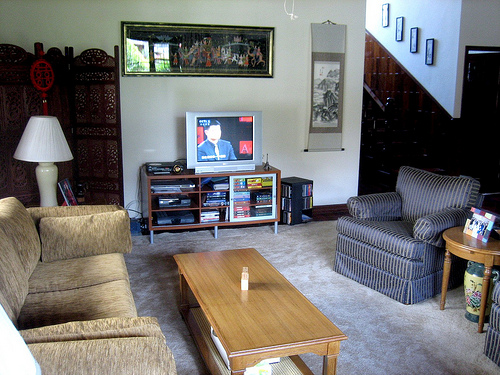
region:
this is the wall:
[138, 99, 159, 121]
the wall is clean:
[149, 99, 163, 126]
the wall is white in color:
[150, 121, 165, 136]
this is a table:
[176, 262, 311, 357]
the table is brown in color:
[235, 301, 275, 341]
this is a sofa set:
[27, 217, 137, 352]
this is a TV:
[186, 104, 263, 162]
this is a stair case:
[395, 57, 425, 108]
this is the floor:
[380, 316, 408, 345]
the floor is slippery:
[366, 332, 395, 358]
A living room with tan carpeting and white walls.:
[3, 1, 499, 374]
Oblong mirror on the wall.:
[116, 22, 274, 82]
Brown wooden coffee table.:
[173, 246, 345, 374]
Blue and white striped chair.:
[332, 161, 485, 303]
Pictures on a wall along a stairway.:
[380, 2, 440, 66]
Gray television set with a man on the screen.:
[184, 114, 266, 174]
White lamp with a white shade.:
[14, 116, 74, 206]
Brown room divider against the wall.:
[0, 38, 124, 215]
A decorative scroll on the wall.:
[300, 18, 350, 155]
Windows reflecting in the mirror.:
[124, 41, 169, 73]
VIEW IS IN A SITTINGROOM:
[103, 144, 351, 372]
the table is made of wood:
[212, 257, 319, 373]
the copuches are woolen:
[32, 245, 115, 360]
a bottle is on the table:
[231, 260, 282, 313]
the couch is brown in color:
[79, 242, 162, 368]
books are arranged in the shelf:
[186, 179, 283, 226]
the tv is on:
[194, 121, 276, 178]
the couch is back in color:
[357, 202, 437, 337]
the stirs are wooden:
[384, 53, 431, 146]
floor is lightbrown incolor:
[360, 315, 422, 373]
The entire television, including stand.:
[182, 110, 261, 170]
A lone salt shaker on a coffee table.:
[237, 263, 247, 292]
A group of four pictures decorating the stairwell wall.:
[380, 1, 433, 66]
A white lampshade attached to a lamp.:
[12, 116, 72, 163]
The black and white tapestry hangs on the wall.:
[304, 15, 347, 154]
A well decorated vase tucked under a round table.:
[465, 260, 498, 324]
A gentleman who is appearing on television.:
[198, 118, 236, 160]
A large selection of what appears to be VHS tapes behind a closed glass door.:
[231, 177, 271, 218]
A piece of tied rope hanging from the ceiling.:
[283, 0, 297, 22]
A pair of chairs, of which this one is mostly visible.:
[324, 165, 479, 302]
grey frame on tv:
[183, 96, 259, 166]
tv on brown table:
[205, 105, 270, 175]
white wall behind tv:
[207, 74, 252, 112]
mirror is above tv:
[120, 23, 273, 88]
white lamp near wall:
[17, 115, 79, 227]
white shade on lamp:
[14, 115, 75, 173]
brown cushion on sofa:
[16, 177, 147, 263]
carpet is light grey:
[316, 240, 405, 350]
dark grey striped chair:
[335, 162, 448, 277]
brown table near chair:
[447, 197, 497, 339]